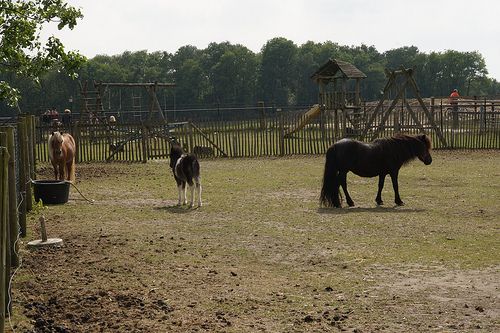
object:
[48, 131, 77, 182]
blonde mane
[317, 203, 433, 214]
dark shadow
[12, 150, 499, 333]
ground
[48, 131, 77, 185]
blonde main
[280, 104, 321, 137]
slide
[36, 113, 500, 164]
fence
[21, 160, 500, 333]
grass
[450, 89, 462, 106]
man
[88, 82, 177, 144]
swingset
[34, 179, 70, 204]
bucket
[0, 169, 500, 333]
field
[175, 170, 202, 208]
legs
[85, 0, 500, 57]
sky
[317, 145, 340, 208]
horse tail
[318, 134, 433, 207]
horse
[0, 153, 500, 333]
pasture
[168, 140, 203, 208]
horse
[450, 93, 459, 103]
top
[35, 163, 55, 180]
hose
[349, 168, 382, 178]
belly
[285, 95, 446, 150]
playground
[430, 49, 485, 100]
tree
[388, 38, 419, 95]
tree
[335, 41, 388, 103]
tree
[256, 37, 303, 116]
tree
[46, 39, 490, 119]
woods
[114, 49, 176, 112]
tree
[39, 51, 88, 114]
tree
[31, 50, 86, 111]
tree